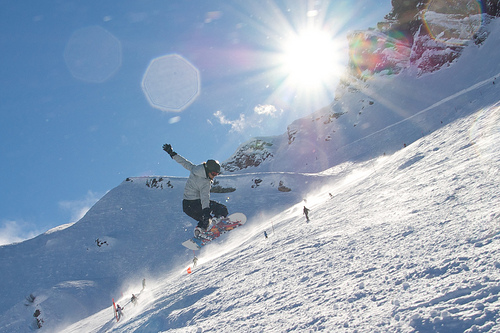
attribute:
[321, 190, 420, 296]
snow — white 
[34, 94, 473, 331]
snow — white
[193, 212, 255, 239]
snowboard — colorful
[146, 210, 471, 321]
snow — white 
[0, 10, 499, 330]
snow — white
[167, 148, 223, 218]
jacket — white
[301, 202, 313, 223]
person — skiing